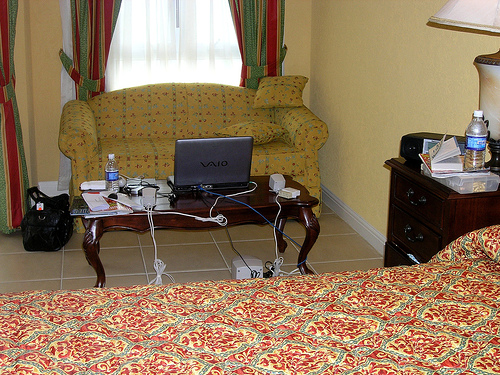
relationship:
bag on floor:
[20, 185, 72, 250] [0, 202, 382, 292]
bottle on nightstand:
[461, 107, 489, 172] [378, 154, 498, 267]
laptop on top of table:
[163, 139, 257, 196] [59, 167, 325, 291]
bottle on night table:
[461, 107, 489, 172] [379, 146, 499, 276]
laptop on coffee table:
[163, 139, 257, 196] [77, 170, 321, 290]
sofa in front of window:
[52, 74, 334, 229] [60, 0, 287, 90]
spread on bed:
[1, 224, 498, 374] [0, 222, 497, 374]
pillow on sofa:
[213, 118, 289, 146] [58, 84, 331, 232]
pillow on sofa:
[254, 73, 306, 110] [58, 84, 331, 232]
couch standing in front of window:
[47, 73, 329, 231] [101, 0, 246, 94]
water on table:
[101, 155, 121, 192] [180, 199, 213, 206]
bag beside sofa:
[20, 185, 72, 250] [16, 49, 358, 252]